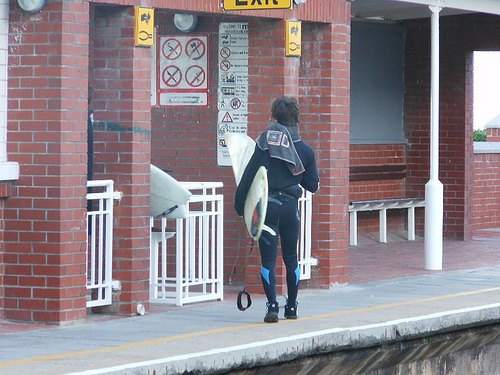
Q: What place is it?
A: It is a pavement.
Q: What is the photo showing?
A: It is showing a pavement.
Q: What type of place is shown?
A: It is a pavement.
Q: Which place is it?
A: It is a pavement.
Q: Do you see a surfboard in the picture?
A: Yes, there is a surfboard.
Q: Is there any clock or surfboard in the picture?
A: Yes, there is a surfboard.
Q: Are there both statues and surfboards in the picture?
A: No, there is a surfboard but no statues.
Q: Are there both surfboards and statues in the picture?
A: No, there is a surfboard but no statues.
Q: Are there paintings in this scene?
A: No, there are no paintings.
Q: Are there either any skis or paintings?
A: No, there are no paintings or skis.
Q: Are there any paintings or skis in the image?
A: No, there are no paintings or skis.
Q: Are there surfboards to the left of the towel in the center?
A: Yes, there is a surfboard to the left of the towel.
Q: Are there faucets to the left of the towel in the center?
A: No, there is a surfboard to the left of the towel.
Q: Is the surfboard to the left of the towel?
A: Yes, the surfboard is to the left of the towel.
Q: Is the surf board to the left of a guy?
A: No, the surf board is to the left of the towel.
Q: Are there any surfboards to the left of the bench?
A: Yes, there is a surfboard to the left of the bench.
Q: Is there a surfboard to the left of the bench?
A: Yes, there is a surfboard to the left of the bench.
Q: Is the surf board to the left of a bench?
A: Yes, the surf board is to the left of a bench.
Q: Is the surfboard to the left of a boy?
A: No, the surfboard is to the left of a bench.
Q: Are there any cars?
A: No, there are no cars.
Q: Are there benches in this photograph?
A: Yes, there is a bench.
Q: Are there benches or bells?
A: Yes, there is a bench.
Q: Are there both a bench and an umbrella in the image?
A: No, there is a bench but no umbrellas.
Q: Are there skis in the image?
A: No, there are no skis.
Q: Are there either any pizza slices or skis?
A: No, there are no skis or pizza slices.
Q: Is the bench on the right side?
A: Yes, the bench is on the right of the image.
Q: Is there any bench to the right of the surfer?
A: Yes, there is a bench to the right of the surfer.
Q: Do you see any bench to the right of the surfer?
A: Yes, there is a bench to the right of the surfer.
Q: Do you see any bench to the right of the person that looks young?
A: Yes, there is a bench to the right of the surfer.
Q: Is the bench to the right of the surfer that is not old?
A: Yes, the bench is to the right of the surfer.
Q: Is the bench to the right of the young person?
A: Yes, the bench is to the right of the surfer.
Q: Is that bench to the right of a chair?
A: No, the bench is to the right of the surfer.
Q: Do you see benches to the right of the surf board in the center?
A: Yes, there is a bench to the right of the surfboard.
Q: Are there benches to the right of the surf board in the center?
A: Yes, there is a bench to the right of the surfboard.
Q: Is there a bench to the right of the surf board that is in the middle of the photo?
A: Yes, there is a bench to the right of the surfboard.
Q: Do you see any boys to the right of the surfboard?
A: No, there is a bench to the right of the surfboard.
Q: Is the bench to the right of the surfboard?
A: Yes, the bench is to the right of the surfboard.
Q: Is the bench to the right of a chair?
A: No, the bench is to the right of the surfboard.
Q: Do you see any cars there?
A: No, there are no cars.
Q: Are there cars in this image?
A: No, there are no cars.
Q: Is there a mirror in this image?
A: No, there are no mirrors.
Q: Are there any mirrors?
A: No, there are no mirrors.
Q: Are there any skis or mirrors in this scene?
A: No, there are no mirrors or skis.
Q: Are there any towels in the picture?
A: Yes, there is a towel.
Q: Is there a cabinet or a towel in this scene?
A: Yes, there is a towel.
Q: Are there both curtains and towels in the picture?
A: No, there is a towel but no curtains.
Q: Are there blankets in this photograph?
A: No, there are no blankets.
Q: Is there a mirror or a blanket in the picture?
A: No, there are no blankets or mirrors.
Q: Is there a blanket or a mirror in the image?
A: No, there are no blankets or mirrors.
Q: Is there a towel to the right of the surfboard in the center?
A: Yes, there is a towel to the right of the surfboard.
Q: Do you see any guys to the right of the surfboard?
A: No, there is a towel to the right of the surfboard.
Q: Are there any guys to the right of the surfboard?
A: No, there is a towel to the right of the surfboard.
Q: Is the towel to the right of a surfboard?
A: Yes, the towel is to the right of a surfboard.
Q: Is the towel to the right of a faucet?
A: No, the towel is to the right of a surfboard.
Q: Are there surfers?
A: Yes, there is a surfer.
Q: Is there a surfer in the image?
A: Yes, there is a surfer.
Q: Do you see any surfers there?
A: Yes, there is a surfer.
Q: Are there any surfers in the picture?
A: Yes, there is a surfer.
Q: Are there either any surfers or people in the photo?
A: Yes, there is a surfer.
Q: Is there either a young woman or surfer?
A: Yes, there is a young surfer.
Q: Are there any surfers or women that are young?
A: Yes, the surfer is young.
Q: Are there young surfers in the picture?
A: Yes, there is a young surfer.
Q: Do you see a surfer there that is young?
A: Yes, there is a surfer that is young.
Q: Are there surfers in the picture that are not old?
A: Yes, there is an young surfer.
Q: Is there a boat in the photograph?
A: No, there are no boats.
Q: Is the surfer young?
A: Yes, the surfer is young.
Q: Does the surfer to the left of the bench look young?
A: Yes, the surfer is young.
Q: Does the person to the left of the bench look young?
A: Yes, the surfer is young.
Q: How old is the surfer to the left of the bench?
A: The surfer is young.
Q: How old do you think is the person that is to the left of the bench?
A: The surfer is young.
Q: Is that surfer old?
A: No, the surfer is young.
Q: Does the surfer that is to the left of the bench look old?
A: No, the surfer is young.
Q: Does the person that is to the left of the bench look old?
A: No, the surfer is young.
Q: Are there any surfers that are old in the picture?
A: No, there is a surfer but he is young.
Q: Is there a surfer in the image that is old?
A: No, there is a surfer but he is young.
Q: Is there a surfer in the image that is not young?
A: No, there is a surfer but he is young.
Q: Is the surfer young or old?
A: The surfer is young.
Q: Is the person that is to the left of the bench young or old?
A: The surfer is young.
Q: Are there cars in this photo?
A: No, there are no cars.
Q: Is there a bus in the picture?
A: No, there are no buses.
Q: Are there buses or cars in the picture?
A: No, there are no buses or cars.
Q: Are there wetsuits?
A: Yes, there is a wetsuit.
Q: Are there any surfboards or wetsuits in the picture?
A: Yes, there is a wetsuit.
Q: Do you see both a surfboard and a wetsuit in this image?
A: Yes, there are both a wetsuit and a surfboard.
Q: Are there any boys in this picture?
A: No, there are no boys.